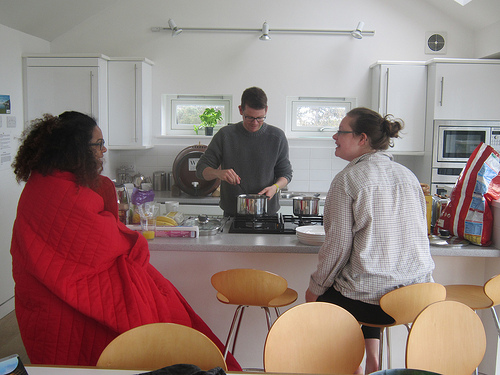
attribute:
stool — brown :
[263, 302, 368, 373]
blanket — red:
[15, 154, 237, 374]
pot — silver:
[237, 192, 267, 213]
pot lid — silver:
[180, 213, 226, 237]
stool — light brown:
[412, 300, 474, 372]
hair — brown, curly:
[10, 111, 92, 186]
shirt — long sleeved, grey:
[196, 121, 292, 213]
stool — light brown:
[210, 268, 298, 362]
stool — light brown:
[207, 265, 303, 372]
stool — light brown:
[357, 281, 447, 371]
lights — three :
[153, 16, 378, 60]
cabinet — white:
[21, 52, 152, 152]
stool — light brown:
[211, 267, 298, 373]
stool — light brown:
[441, 274, 498, 306]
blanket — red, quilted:
[7, 166, 242, 371]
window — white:
[155, 90, 233, 139]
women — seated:
[14, 99, 440, 369]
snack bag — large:
[435, 137, 498, 249]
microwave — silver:
[436, 116, 498, 172]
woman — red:
[16, 115, 175, 332]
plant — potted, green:
[198, 102, 224, 125]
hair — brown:
[241, 89, 280, 110]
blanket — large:
[7, 171, 212, 338]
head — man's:
[229, 87, 273, 137]